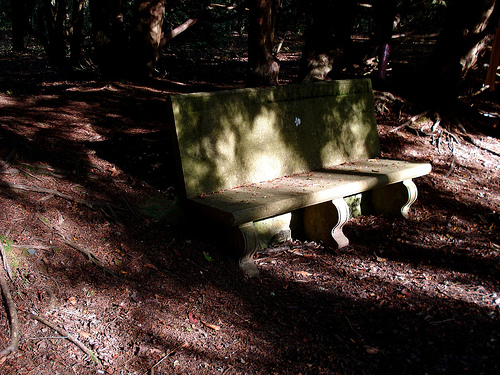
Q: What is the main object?
A: A cement bench.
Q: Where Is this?
A: A wooded area.